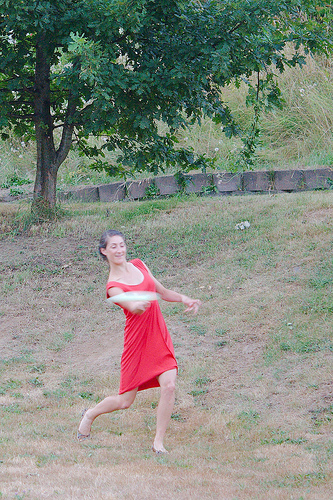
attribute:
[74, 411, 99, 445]
shoe — here, flat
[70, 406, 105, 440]
foot — here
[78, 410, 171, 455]
shoes — flat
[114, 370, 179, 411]
knees — crinkly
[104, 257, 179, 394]
dress — red, here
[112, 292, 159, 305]
frisbee — white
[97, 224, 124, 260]
hair — dark, short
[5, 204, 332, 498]
grass — dry, here, tan, brown, green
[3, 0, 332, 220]
tree — full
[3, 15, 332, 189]
grass — tall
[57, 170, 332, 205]
wall — stone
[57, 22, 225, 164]
branch — low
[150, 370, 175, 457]
leg — here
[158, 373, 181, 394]
knee — here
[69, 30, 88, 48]
leaf — green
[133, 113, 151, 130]
leaf — green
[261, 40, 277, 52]
leaf — green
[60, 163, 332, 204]
stones — square